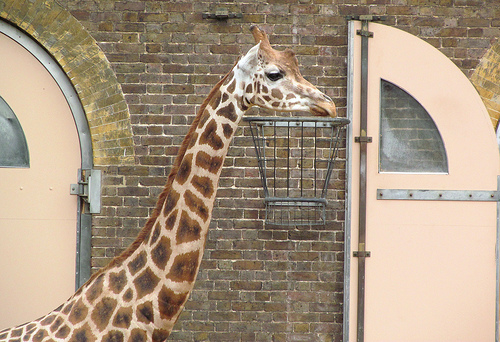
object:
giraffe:
[182, 37, 340, 179]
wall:
[0, 0, 500, 340]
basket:
[243, 112, 349, 226]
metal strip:
[367, 185, 498, 202]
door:
[347, 17, 498, 340]